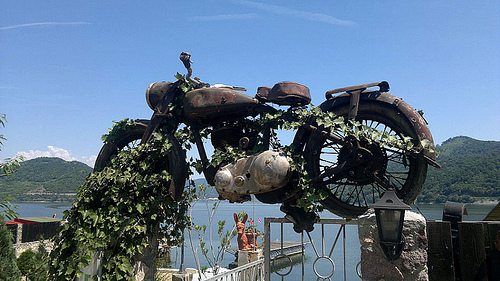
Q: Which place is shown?
A: It is a lake.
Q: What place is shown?
A: It is a lake.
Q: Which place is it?
A: It is a lake.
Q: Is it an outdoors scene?
A: Yes, it is outdoors.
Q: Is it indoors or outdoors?
A: It is outdoors.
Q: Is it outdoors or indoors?
A: It is outdoors.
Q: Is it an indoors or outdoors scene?
A: It is outdoors.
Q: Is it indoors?
A: No, it is outdoors.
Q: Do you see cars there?
A: No, there are no cars.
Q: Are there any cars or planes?
A: No, there are no cars or planes.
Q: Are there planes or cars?
A: No, there are no cars or planes.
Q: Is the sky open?
A: Yes, the sky is open.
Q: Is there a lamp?
A: Yes, there is a lamp.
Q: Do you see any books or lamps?
A: Yes, there is a lamp.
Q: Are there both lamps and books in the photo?
A: No, there is a lamp but no books.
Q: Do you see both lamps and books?
A: No, there is a lamp but no books.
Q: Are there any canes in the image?
A: No, there are no canes.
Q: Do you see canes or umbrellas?
A: No, there are no canes or umbrellas.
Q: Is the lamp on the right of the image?
A: Yes, the lamp is on the right of the image.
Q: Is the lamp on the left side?
A: No, the lamp is on the right of the image.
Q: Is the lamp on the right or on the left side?
A: The lamp is on the right of the image.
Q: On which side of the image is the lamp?
A: The lamp is on the right of the image.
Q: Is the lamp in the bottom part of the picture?
A: Yes, the lamp is in the bottom of the image.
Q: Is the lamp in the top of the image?
A: No, the lamp is in the bottom of the image.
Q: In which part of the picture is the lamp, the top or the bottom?
A: The lamp is in the bottom of the image.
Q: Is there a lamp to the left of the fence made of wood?
A: Yes, there is a lamp to the left of the fence.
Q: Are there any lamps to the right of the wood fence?
A: No, the lamp is to the left of the fence.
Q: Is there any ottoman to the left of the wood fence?
A: No, there is a lamp to the left of the fence.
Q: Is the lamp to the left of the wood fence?
A: Yes, the lamp is to the left of the fence.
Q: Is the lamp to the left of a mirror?
A: No, the lamp is to the left of the fence.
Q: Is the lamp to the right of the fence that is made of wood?
A: No, the lamp is to the left of the fence.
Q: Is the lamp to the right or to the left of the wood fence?
A: The lamp is to the left of the fence.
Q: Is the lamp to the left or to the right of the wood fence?
A: The lamp is to the left of the fence.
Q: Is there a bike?
A: Yes, there is a bike.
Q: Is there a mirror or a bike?
A: Yes, there is a bike.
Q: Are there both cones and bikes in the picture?
A: No, there is a bike but no cones.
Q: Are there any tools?
A: No, there are no tools.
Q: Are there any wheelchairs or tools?
A: No, there are no tools or wheelchairs.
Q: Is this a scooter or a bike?
A: This is a bike.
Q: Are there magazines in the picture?
A: No, there are no magazines.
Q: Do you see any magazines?
A: No, there are no magazines.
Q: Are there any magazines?
A: No, there are no magazines.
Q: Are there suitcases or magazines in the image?
A: No, there are no magazines or suitcases.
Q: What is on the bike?
A: The seat is on the bike.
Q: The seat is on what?
A: The seat is on the bike.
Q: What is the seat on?
A: The seat is on the bike.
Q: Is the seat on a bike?
A: Yes, the seat is on a bike.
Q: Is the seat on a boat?
A: No, the seat is on a bike.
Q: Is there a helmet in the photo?
A: No, there are no helmets.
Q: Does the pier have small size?
A: Yes, the pier is small.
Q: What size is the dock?
A: The dock is small.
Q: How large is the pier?
A: The pier is small.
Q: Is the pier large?
A: No, the pier is small.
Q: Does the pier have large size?
A: No, the pier is small.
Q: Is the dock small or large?
A: The dock is small.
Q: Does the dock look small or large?
A: The dock is small.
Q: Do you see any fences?
A: Yes, there is a fence.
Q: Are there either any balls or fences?
A: Yes, there is a fence.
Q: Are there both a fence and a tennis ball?
A: No, there is a fence but no tennis balls.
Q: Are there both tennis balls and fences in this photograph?
A: No, there is a fence but no tennis balls.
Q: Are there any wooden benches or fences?
A: Yes, there is a wood fence.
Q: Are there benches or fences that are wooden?
A: Yes, the fence is wooden.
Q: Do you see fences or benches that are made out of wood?
A: Yes, the fence is made of wood.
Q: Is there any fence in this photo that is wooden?
A: Yes, there is a wood fence.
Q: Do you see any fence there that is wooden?
A: Yes, there is a fence that is wooden.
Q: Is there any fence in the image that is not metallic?
A: Yes, there is a wooden fence.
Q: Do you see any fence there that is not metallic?
A: Yes, there is a wooden fence.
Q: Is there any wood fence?
A: Yes, there is a fence that is made of wood.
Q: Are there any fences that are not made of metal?
A: Yes, there is a fence that is made of wood.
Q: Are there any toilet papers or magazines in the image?
A: No, there are no magazines or toilet papers.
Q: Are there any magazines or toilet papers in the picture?
A: No, there are no magazines or toilet papers.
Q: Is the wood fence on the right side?
A: Yes, the fence is on the right of the image.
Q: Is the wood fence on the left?
A: No, the fence is on the right of the image.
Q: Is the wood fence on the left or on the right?
A: The fence is on the right of the image.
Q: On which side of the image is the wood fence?
A: The fence is on the right of the image.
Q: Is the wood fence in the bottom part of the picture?
A: Yes, the fence is in the bottom of the image.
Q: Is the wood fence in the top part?
A: No, the fence is in the bottom of the image.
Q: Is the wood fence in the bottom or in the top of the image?
A: The fence is in the bottom of the image.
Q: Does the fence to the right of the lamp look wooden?
A: Yes, the fence is wooden.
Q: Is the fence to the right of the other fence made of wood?
A: Yes, the fence is made of wood.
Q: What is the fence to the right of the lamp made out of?
A: The fence is made of wood.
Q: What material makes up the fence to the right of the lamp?
A: The fence is made of wood.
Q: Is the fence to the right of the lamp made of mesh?
A: No, the fence is made of wood.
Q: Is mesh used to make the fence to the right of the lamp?
A: No, the fence is made of wood.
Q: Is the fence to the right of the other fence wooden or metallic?
A: The fence is wooden.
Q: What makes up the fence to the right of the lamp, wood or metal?
A: The fence is made of wood.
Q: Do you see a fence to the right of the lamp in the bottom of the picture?
A: Yes, there is a fence to the right of the lamp.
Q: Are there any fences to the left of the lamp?
A: No, the fence is to the right of the lamp.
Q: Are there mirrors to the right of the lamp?
A: No, there is a fence to the right of the lamp.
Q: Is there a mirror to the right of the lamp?
A: No, there is a fence to the right of the lamp.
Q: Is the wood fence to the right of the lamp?
A: Yes, the fence is to the right of the lamp.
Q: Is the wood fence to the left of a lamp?
A: No, the fence is to the right of a lamp.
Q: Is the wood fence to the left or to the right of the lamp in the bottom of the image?
A: The fence is to the right of the lamp.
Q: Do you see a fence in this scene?
A: Yes, there is a fence.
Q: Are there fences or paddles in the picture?
A: Yes, there is a fence.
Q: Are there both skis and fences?
A: No, there is a fence but no skis.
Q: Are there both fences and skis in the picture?
A: No, there is a fence but no skis.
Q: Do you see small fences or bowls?
A: Yes, there is a small fence.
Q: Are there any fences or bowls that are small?
A: Yes, the fence is small.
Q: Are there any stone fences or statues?
A: Yes, there is a stone fence.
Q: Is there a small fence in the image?
A: Yes, there is a small fence.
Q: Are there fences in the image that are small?
A: Yes, there is a fence that is small.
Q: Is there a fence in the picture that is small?
A: Yes, there is a fence that is small.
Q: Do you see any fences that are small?
A: Yes, there is a fence that is small.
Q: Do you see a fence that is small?
A: Yes, there is a fence that is small.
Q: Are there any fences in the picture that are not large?
A: Yes, there is a small fence.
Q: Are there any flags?
A: No, there are no flags.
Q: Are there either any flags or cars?
A: No, there are no flags or cars.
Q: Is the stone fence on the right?
A: Yes, the fence is on the right of the image.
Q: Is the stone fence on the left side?
A: No, the fence is on the right of the image.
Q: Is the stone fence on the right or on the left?
A: The fence is on the right of the image.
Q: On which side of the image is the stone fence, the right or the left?
A: The fence is on the right of the image.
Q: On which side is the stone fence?
A: The fence is on the right of the image.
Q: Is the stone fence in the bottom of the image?
A: Yes, the fence is in the bottom of the image.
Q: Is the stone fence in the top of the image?
A: No, the fence is in the bottom of the image.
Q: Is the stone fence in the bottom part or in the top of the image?
A: The fence is in the bottom of the image.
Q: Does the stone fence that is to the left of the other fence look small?
A: Yes, the fence is small.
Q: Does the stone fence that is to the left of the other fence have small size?
A: Yes, the fence is small.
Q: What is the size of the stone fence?
A: The fence is small.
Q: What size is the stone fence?
A: The fence is small.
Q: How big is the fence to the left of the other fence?
A: The fence is small.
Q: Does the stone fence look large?
A: No, the fence is small.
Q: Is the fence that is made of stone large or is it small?
A: The fence is small.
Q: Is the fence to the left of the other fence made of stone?
A: Yes, the fence is made of stone.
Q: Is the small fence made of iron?
A: No, the fence is made of stone.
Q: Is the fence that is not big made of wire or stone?
A: The fence is made of stone.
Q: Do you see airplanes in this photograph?
A: No, there are no airplanes.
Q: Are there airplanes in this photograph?
A: No, there are no airplanes.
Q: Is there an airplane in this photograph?
A: No, there are no airplanes.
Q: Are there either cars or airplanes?
A: No, there are no airplanes or cars.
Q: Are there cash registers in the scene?
A: No, there are no cash registers.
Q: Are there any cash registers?
A: No, there are no cash registers.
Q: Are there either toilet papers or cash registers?
A: No, there are no cash registers or toilet papers.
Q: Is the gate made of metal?
A: Yes, the gate is made of metal.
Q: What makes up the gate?
A: The gate is made of metal.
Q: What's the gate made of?
A: The gate is made of metal.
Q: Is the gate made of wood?
A: No, the gate is made of metal.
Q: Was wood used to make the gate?
A: No, the gate is made of metal.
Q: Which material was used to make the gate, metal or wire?
A: The gate is made of metal.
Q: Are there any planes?
A: No, there are no planes.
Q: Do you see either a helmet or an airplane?
A: No, there are no airplanes or helmets.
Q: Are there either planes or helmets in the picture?
A: No, there are no planes or helmets.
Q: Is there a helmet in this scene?
A: No, there are no helmets.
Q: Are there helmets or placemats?
A: No, there are no helmets or placemats.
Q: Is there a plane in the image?
A: No, there are no airplanes.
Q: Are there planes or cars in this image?
A: No, there are no planes or cars.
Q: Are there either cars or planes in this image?
A: No, there are no planes or cars.